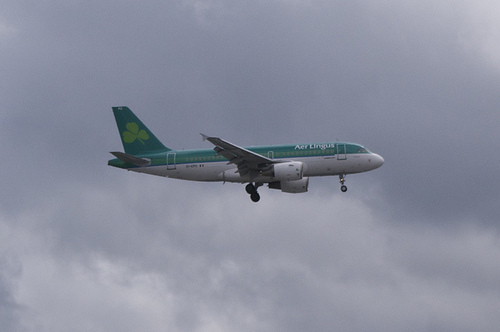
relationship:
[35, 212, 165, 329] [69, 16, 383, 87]
clouds in sky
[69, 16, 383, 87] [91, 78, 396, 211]
sky behind plane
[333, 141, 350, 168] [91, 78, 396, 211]
door of plane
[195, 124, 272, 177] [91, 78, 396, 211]
wing of plane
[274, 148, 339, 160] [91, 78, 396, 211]
windows of plane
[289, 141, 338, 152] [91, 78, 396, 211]
writing on plane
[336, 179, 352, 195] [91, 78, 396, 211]
tires on plane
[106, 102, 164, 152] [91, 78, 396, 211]
tail on plane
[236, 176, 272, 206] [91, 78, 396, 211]
wheels on plane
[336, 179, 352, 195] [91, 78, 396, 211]
wheel on plane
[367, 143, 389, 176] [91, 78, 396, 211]
nose of plane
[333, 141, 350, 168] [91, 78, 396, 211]
door on plane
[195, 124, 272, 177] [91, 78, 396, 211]
wing on plane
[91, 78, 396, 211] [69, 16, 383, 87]
plane in sky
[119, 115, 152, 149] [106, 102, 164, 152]
clover on tail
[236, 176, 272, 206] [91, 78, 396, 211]
wheels under plane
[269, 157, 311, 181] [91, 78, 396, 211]
enigine on plane